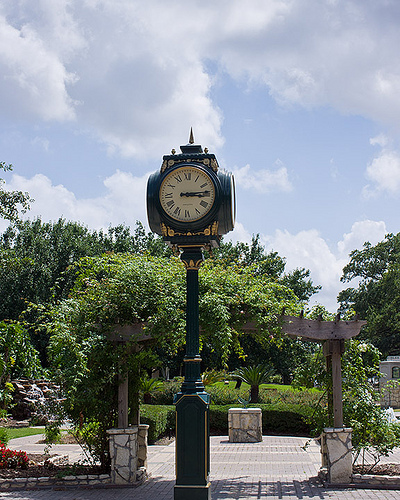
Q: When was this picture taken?
A: Daytime.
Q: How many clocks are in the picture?
A: One.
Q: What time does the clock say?
A: 3:14.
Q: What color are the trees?
A: Green.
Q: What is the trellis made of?
A: Wood.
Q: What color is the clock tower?
A: Green and yellow.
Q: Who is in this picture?
A: No one.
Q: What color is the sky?
A: Blue.